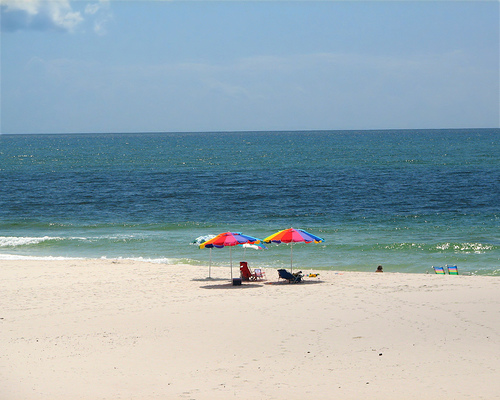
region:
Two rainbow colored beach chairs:
[430, 255, 463, 284]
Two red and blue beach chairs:
[236, 253, 310, 297]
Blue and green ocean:
[20, 127, 490, 269]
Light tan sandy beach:
[15, 252, 497, 394]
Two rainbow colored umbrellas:
[202, 214, 317, 252]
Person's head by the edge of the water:
[372, 260, 387, 275]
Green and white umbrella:
[185, 229, 217, 284]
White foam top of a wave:
[0, 233, 51, 248]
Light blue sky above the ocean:
[5, 15, 480, 129]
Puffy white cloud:
[0, 6, 96, 46]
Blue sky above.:
[49, 1, 403, 132]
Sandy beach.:
[36, 269, 484, 390]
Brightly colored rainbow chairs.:
[432, 262, 458, 276]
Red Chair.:
[237, 261, 261, 281]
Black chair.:
[278, 266, 304, 287]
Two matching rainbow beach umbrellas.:
[201, 226, 321, 256]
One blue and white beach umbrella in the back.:
[193, 229, 213, 247]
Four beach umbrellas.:
[198, 222, 316, 255]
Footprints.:
[340, 278, 491, 388]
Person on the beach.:
[373, 260, 384, 277]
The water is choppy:
[2, 133, 497, 275]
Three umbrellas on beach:
[190, 227, 324, 286]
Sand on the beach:
[1, 254, 498, 399]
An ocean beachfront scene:
[1, 133, 498, 398]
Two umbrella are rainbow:
[203, 226, 323, 293]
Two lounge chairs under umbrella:
[231, 261, 321, 289]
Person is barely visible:
[373, 263, 387, 278]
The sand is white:
[2, 253, 498, 398]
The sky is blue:
[1, 1, 499, 131]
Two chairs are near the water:
[428, 263, 467, 279]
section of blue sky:
[291, 45, 379, 112]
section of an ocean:
[123, 157, 178, 187]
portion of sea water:
[316, 145, 358, 177]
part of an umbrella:
[285, 227, 297, 241]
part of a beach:
[231, 314, 311, 341]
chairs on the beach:
[448, 266, 457, 273]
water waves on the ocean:
[32, 238, 80, 251]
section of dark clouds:
[44, 11, 56, 21]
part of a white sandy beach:
[266, 332, 346, 362]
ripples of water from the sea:
[21, 236, 42, 241]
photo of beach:
[29, 31, 479, 391]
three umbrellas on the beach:
[192, 204, 364, 321]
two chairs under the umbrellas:
[236, 203, 334, 301]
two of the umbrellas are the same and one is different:
[186, 217, 329, 297]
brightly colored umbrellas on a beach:
[198, 204, 333, 309]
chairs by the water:
[418, 257, 489, 298]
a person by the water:
[368, 252, 408, 276]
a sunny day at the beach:
[31, 96, 449, 398]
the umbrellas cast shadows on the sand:
[186, 210, 352, 305]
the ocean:
[2, 122, 497, 292]